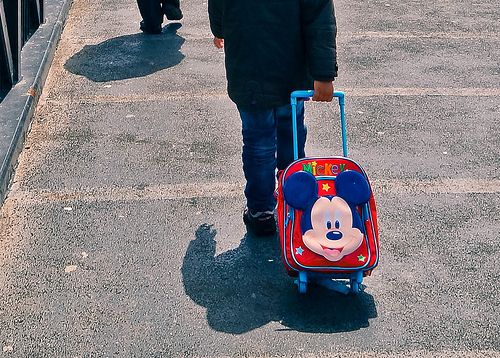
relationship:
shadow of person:
[180, 222, 378, 335] [207, 1, 338, 238]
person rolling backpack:
[207, 1, 338, 238] [273, 91, 380, 295]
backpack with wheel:
[273, 91, 380, 295] [293, 270, 308, 292]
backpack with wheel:
[273, 91, 380, 295] [349, 270, 366, 293]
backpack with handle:
[273, 91, 380, 295] [290, 89, 349, 161]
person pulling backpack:
[207, 1, 338, 238] [273, 91, 380, 295]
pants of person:
[236, 102, 306, 210] [207, 1, 338, 238]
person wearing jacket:
[207, 1, 338, 238] [208, 0, 339, 111]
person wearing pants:
[207, 1, 338, 238] [236, 102, 306, 210]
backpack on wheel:
[273, 91, 380, 295] [293, 270, 308, 292]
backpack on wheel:
[273, 91, 380, 295] [349, 270, 366, 293]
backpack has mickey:
[273, 91, 380, 295] [283, 169, 371, 261]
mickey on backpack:
[283, 169, 371, 261] [273, 91, 380, 295]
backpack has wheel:
[273, 91, 380, 295] [293, 270, 308, 292]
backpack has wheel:
[273, 91, 380, 295] [349, 270, 366, 293]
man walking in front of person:
[136, 0, 183, 34] [207, 1, 338, 238]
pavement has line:
[0, 0, 500, 357] [60, 29, 499, 42]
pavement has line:
[0, 0, 500, 357] [38, 87, 499, 104]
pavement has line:
[0, 0, 500, 357] [3, 179, 500, 205]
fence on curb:
[1, 0, 45, 102] [0, 0, 73, 205]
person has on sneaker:
[207, 1, 338, 238] [243, 202, 277, 237]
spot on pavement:
[105, 84, 112, 90] [0, 0, 500, 357]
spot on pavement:
[124, 113, 136, 119] [0, 0, 500, 357]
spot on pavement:
[64, 205, 72, 211] [0, 0, 500, 357]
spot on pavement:
[82, 251, 88, 258] [0, 0, 500, 357]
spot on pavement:
[64, 264, 79, 275] [0, 0, 500, 357]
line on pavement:
[60, 29, 499, 42] [0, 0, 500, 357]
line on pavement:
[38, 87, 499, 104] [0, 0, 500, 357]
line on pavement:
[3, 179, 500, 205] [0, 0, 500, 357]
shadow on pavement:
[180, 222, 378, 335] [0, 0, 500, 357]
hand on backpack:
[312, 80, 334, 101] [273, 91, 380, 295]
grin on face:
[319, 244, 345, 259] [302, 195, 365, 262]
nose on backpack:
[325, 230, 343, 241] [273, 91, 380, 295]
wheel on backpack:
[293, 270, 308, 292] [273, 91, 380, 295]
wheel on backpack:
[349, 270, 366, 293] [273, 91, 380, 295]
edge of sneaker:
[248, 210, 275, 218] [243, 202, 277, 237]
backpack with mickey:
[273, 91, 380, 295] [283, 169, 371, 261]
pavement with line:
[0, 0, 500, 357] [60, 29, 499, 42]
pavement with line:
[0, 0, 500, 357] [38, 87, 499, 104]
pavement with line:
[0, 0, 500, 357] [3, 179, 500, 205]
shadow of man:
[64, 22, 185, 82] [136, 0, 183, 34]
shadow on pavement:
[64, 22, 185, 82] [0, 0, 500, 357]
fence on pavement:
[1, 0, 45, 102] [0, 0, 500, 357]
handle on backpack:
[290, 89, 349, 161] [273, 91, 380, 295]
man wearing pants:
[136, 0, 183, 34] [136, 0, 181, 25]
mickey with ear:
[283, 169, 371, 261] [282, 170, 318, 210]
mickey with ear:
[283, 169, 371, 261] [335, 169, 370, 205]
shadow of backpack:
[180, 222, 378, 335] [273, 91, 380, 295]